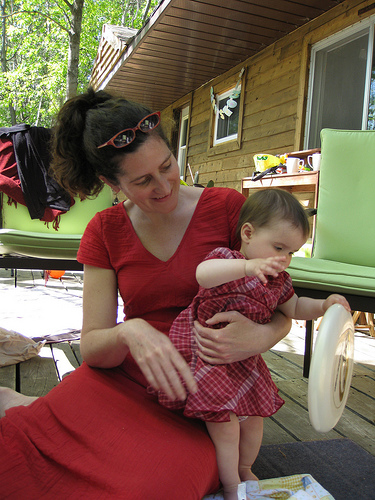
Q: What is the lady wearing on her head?
A: Eyeglasses.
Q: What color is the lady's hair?
A: Dark brown.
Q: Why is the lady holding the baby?
A: So she does not fall.